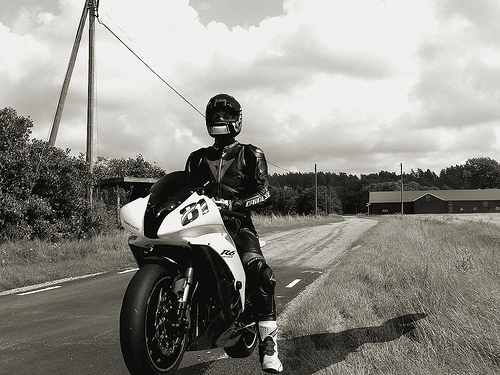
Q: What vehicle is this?
A: Motorcycle.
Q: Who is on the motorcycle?
A: The man.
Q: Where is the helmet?
A: On the man's head.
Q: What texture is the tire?
A: Smooth.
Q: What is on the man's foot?
A: Boot.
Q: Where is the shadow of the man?
A: On the ground.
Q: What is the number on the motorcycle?
A: 81.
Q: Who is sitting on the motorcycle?
A: A man in a black suit.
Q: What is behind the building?
A: Trees.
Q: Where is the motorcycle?
A: Pavement.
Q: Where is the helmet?
A: On the man's head.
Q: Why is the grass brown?
A: It is dry.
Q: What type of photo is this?
A: Black and white.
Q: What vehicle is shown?
A: Motorcycle.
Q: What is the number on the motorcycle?
A: 81.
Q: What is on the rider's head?
A: Helmet.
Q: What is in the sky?
A: Clouds.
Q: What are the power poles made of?
A: Wood.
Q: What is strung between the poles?
A: Power lines.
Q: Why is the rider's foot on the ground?
A: Balance the bike.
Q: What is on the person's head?
A: Helmet.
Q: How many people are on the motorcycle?
A: One.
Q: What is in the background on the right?
A: House.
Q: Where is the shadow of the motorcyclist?
A: On ground on right.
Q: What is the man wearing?
A: A leather outfit.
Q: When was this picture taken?
A: Daytime.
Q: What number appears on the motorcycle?
A: 81.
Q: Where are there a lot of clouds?
A: In the sky.